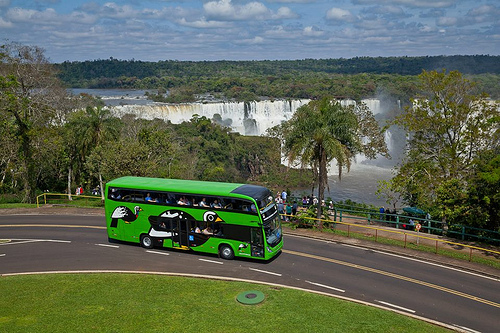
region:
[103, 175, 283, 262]
a double decker green bus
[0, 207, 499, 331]
a paved two lane road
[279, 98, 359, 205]
large green tree in distance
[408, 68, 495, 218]
large green tree in distance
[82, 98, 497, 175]
a large waterfall in distance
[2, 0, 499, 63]
a cloudy blue sky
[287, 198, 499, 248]
a long green fence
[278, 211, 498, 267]
a long yellow fence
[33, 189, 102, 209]
a long yellow fence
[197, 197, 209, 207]
a passenger on bus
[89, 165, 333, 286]
This is a bus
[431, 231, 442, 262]
This is a shot pole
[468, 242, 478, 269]
This is a shot pole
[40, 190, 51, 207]
This is a shot pole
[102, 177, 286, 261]
a green bus on the street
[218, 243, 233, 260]
the tire of a bus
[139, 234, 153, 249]
the tire of a bus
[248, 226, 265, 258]
the door of a bus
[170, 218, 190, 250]
the door of a bus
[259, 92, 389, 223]
a large green tree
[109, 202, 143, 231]
the drawing of a bird on a bus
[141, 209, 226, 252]
the drawing of a bird on a bus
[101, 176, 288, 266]
a large green bus driving down a curve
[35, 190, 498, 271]
a long yellow fence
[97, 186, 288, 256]
a large green tour bus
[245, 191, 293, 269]
the front of a tour bus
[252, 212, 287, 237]
the front window of a tour bus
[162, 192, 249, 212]
the second story of a tour bus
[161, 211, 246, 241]
the first story of a tour bus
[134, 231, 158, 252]
the back wheel of a tour bus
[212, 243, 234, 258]
the front wheel of tour bus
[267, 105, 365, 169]
a large tree with many leaves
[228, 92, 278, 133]
a large lake with water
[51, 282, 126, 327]
a large patch of green grass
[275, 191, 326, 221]
people standing on the sidewalk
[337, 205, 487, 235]
a green fence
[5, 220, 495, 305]
the street the bus is driving on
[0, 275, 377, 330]
grass next to the street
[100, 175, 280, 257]
a green bus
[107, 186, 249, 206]
the windows on the bus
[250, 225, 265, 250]
the door on the bus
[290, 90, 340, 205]
a tree behind the bus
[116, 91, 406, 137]
a large waterfall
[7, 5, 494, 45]
the sky above the water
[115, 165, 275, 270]
the bus is double decker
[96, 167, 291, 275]
Green bus on the road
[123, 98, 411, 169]
Waterfall in the background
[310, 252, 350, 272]
Yellow lines on the road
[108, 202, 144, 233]
Bird on the bus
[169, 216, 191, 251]
Doors on a bus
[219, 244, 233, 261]
Tires on a bus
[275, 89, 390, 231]
Tree by a fence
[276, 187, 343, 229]
Group of people by a fence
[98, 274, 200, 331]
Neatly trimmed grass by a road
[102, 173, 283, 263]
the bus is green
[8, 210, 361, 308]
the road is curving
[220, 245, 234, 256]
gray rim of a wheel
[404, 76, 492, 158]
tree with green leaves